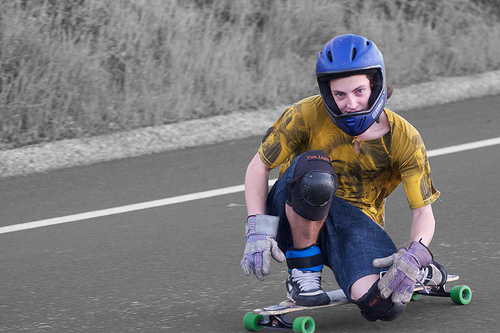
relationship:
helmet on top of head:
[316, 34, 390, 137] [324, 57, 381, 124]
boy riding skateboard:
[242, 33, 446, 321] [242, 273, 473, 332]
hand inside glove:
[249, 232, 269, 267] [242, 216, 286, 282]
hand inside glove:
[381, 256, 421, 298] [372, 237, 435, 306]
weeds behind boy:
[1, 1, 499, 152] [242, 33, 446, 321]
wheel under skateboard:
[411, 291, 423, 300] [242, 273, 473, 332]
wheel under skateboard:
[292, 316, 315, 332] [242, 273, 473, 332]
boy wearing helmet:
[242, 33, 446, 321] [316, 34, 390, 137]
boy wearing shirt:
[242, 33, 446, 321] [258, 93, 439, 229]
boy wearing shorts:
[242, 33, 446, 321] [267, 153, 410, 306]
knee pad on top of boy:
[288, 152, 337, 221] [242, 33, 446, 321]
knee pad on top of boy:
[351, 279, 410, 321] [242, 33, 446, 321]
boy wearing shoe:
[242, 33, 446, 321] [286, 268, 334, 307]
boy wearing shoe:
[242, 33, 446, 321] [388, 262, 447, 288]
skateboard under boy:
[242, 273, 473, 332] [242, 33, 446, 321]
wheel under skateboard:
[244, 310, 264, 330] [242, 273, 473, 332]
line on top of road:
[2, 135, 499, 235] [2, 94, 497, 331]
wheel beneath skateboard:
[411, 291, 423, 300] [242, 273, 473, 332]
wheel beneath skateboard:
[292, 316, 315, 332] [242, 273, 473, 332]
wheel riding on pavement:
[411, 291, 423, 300] [2, 94, 497, 331]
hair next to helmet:
[368, 74, 389, 103] [316, 34, 390, 137]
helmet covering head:
[316, 34, 390, 137] [324, 57, 381, 124]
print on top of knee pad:
[306, 154, 332, 161] [288, 152, 337, 221]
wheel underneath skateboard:
[411, 291, 423, 300] [242, 273, 473, 332]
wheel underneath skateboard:
[292, 316, 315, 332] [242, 273, 473, 332]